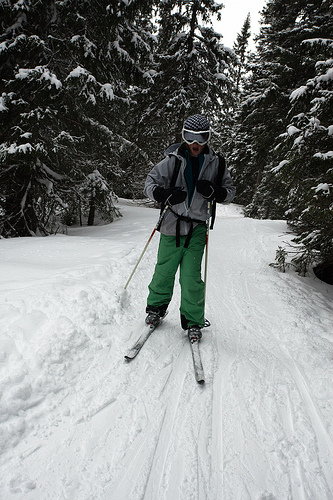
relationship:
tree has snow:
[4, 2, 122, 234] [67, 67, 96, 92]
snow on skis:
[193, 347, 200, 362] [129, 320, 211, 385]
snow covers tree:
[67, 67, 96, 92] [4, 2, 122, 234]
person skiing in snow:
[117, 115, 243, 394] [23, 390, 315, 496]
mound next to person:
[0, 270, 86, 430] [117, 115, 243, 394]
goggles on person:
[177, 126, 211, 148] [117, 115, 243, 394]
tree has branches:
[4, 2, 122, 234] [67, 106, 120, 146]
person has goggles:
[117, 115, 243, 394] [177, 126, 211, 148]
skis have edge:
[129, 320, 211, 385] [199, 354, 212, 386]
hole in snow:
[3, 472, 28, 497] [23, 390, 315, 496]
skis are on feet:
[129, 320, 211, 385] [146, 305, 204, 341]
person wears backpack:
[117, 115, 243, 394] [161, 139, 182, 188]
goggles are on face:
[177, 126, 211, 148] [182, 128, 211, 157]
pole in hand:
[116, 203, 174, 295] [157, 185, 188, 206]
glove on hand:
[155, 183, 190, 208] [157, 185, 188, 206]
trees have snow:
[3, 4, 329, 229] [67, 67, 96, 92]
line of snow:
[144, 406, 167, 498] [23, 390, 315, 496]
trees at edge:
[3, 4, 329, 229] [235, 163, 332, 284]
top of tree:
[234, 13, 257, 43] [222, 15, 252, 196]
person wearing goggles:
[117, 115, 243, 394] [177, 126, 211, 148]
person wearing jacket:
[117, 115, 243, 394] [146, 149, 238, 233]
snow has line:
[23, 390, 315, 496] [144, 406, 167, 498]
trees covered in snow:
[3, 4, 329, 229] [67, 67, 96, 92]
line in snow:
[271, 330, 328, 484] [23, 390, 315, 496]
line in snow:
[202, 343, 224, 497] [23, 390, 315, 496]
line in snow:
[149, 355, 186, 499] [23, 390, 315, 496]